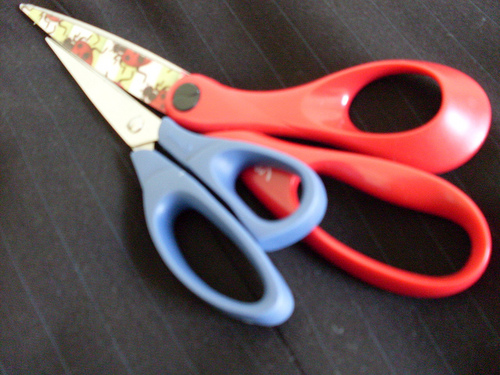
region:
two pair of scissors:
[21, 4, 491, 326]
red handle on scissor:
[181, 56, 492, 301]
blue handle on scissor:
[134, 114, 328, 328]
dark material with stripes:
[5, 2, 495, 369]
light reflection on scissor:
[448, 108, 481, 148]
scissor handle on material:
[117, 173, 182, 312]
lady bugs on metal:
[32, 12, 158, 89]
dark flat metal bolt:
[170, 81, 201, 115]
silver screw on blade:
[127, 114, 147, 135]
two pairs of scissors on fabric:
[10, 0, 490, 330]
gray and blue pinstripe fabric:
[10, 185, 130, 361]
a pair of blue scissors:
[40, 35, 326, 325]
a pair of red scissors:
[16, 0, 487, 292]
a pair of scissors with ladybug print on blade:
[20, 1, 490, 296]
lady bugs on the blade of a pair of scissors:
[15, 2, 180, 110]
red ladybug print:
[110, 40, 150, 75]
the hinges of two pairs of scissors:
[122, 75, 217, 137]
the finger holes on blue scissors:
[155, 145, 311, 318]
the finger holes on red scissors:
[280, 63, 483, 289]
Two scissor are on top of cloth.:
[68, 29, 374, 248]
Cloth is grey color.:
[13, 192, 153, 374]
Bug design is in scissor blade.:
[42, 5, 182, 101]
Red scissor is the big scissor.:
[23, 4, 427, 212]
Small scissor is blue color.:
[43, 42, 323, 294]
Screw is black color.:
[169, 74, 209, 126]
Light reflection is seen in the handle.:
[413, 82, 495, 168]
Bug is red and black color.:
[73, 37, 100, 67]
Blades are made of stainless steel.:
[31, 11, 164, 136]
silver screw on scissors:
[130, 115, 147, 135]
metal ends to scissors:
[25, 36, 165, 141]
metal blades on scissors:
[28, 30, 170, 142]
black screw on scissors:
[169, 86, 199, 113]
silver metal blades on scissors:
[8, 0, 178, 108]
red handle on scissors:
[166, 53, 493, 132]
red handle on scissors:
[192, 140, 479, 320]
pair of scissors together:
[0, 0, 484, 237]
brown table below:
[0, 163, 92, 270]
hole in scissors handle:
[349, 64, 441, 136]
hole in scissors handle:
[228, 156, 305, 223]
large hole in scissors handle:
[165, 200, 260, 312]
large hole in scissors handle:
[295, 165, 475, 280]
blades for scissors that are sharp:
[42, 35, 160, 145]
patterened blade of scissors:
[20, 5, 181, 112]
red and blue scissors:
[16, 3, 495, 321]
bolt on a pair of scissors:
[126, 118, 144, 132]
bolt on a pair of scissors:
[171, 83, 197, 112]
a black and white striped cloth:
[2, 1, 497, 373]